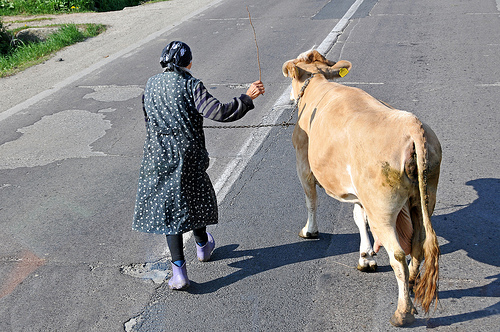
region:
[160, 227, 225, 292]
Woman wearing shoes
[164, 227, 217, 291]
Woman is wearing shoes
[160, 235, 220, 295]
Woman wearing purple shoes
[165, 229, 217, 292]
Woman is wearing purple shoes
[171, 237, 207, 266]
Woman wearing socks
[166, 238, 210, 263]
Woman is wearing socks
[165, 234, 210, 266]
Woman wearing blue socks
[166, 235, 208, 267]
Woman is wearing blue socks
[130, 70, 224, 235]
Woman wearing a dress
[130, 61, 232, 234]
Woman is wearing a dress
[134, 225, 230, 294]
the boots are purple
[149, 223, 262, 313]
the boots are purple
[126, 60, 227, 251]
woman is wearing a dress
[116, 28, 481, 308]
woman walking a cow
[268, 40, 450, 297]
brown cow walking down the street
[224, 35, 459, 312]
cow wearing a chain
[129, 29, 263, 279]
woman wearing a blue coat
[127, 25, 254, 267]
woman wearing a scarf on her head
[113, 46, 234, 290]
woman wearing purple boots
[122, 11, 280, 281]
woman holding a stick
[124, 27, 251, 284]
woman wearing blue socks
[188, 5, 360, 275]
line in middle of the road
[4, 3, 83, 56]
grass on side of the road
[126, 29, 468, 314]
a woman with a cow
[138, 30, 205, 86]
a woman with a bandana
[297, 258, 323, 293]
Small part of a black street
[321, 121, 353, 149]
Small part of the skin of a brown cow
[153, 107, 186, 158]
Medium section of the lady's blue and white jacket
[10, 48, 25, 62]
Small patch of green grass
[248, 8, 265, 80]
Small brown stick that the woman is holding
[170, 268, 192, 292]
Left gray sneakers of woman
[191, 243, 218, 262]
Right gray sneakers of the woman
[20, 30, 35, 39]
Small part of a gray rock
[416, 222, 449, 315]
Brown tail of the cow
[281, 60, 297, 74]
Left ear of the cow